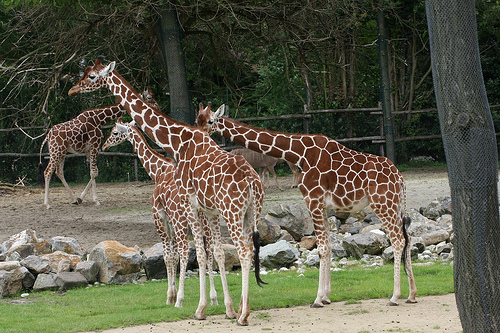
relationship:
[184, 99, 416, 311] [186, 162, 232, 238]
group has spots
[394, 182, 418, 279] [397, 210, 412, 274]
tail with a tuft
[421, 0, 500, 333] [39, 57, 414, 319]
trunk near giraffes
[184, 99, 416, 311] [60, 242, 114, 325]
group facing left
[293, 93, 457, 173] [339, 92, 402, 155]
fence made of sticks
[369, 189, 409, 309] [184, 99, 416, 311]
leg of group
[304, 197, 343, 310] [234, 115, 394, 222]
leg of giraffe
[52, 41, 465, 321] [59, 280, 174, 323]
giraffes are standing on grass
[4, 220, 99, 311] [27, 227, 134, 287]
piled up rocks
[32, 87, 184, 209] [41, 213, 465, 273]
giraffe walking in background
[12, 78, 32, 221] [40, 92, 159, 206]
tree trunk beside background giraffe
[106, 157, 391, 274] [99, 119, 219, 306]
group of three giraffe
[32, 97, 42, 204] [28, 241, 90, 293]
tree trunk covered with wire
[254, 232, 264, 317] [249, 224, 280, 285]
hair at end of tail